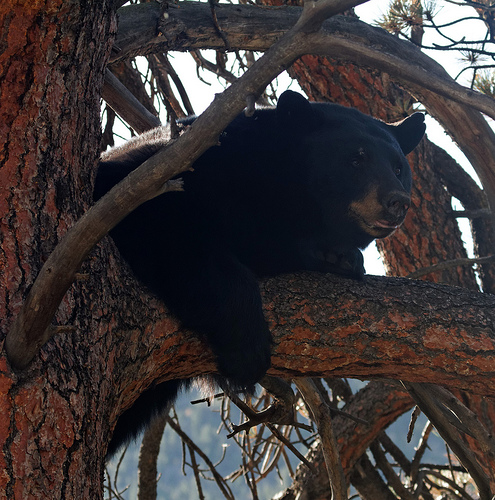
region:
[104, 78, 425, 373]
the bear is big and black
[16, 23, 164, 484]
the tree has big branches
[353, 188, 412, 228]
The black bear has a brown mouth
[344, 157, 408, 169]
the bear has two big brown eyes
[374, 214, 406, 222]
the bear has a pink tongue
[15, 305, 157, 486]
the tree has red and brown color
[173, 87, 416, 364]
the bear is fat and big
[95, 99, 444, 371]
the bear is laying on the branch.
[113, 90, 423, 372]
the bear is laying in the tree looking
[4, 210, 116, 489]
the tree branches look like scales.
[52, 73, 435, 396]
black bear in the tree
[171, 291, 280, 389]
paw of the bear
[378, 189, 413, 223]
black nose on the bear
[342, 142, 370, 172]
eye of the bear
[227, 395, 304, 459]
brown sticks on the tree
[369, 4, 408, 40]
pine needles on the tree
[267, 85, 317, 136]
left ear on the bear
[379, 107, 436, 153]
right ear on the bear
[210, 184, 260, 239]
black on the bear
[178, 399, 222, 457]
white clouds through the trees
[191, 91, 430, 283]
A bear perched on a tree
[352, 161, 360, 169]
The eye of a bear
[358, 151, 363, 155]
A greyish mark above the eye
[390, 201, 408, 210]
The nostrils of the bear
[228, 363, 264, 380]
Paw hanging over the limb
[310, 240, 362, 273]
Paw on the branch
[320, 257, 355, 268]
The claws on the paw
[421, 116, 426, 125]
A tear in the ear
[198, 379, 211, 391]
Fur reflecting in the light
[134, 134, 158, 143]
Light reflecting on the back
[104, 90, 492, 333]
The bear is in the tree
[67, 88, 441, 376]
The bear is black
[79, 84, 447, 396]
The bear is alone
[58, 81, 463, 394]
There is only one bear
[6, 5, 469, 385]
The tree is red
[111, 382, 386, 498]
There are several branches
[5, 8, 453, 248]
The photo is taken during the day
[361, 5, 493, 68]
There are pines on the trees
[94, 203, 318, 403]
The bear's paw is on the branch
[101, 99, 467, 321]
The bear is between branches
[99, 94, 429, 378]
the bear is in a tree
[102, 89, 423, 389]
the bear is black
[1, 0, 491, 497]
the tree is brown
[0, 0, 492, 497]
the scene takes place outdoors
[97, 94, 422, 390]
the animal is on a branch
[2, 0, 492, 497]
the scene takes place during the day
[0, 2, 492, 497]
the animal is in the wilderness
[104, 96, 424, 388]
the bear is on a branch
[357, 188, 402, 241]
the bear has a brown mouth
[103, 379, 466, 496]
the sun in shining